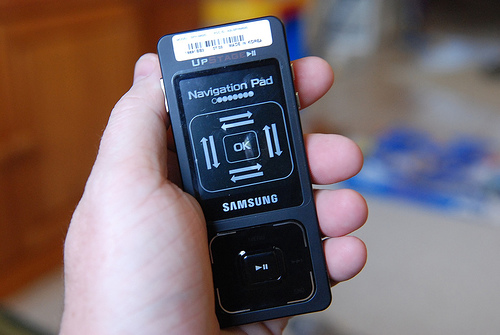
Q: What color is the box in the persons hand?
A: Black.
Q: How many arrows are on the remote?
A: 8.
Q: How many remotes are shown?
A: 1.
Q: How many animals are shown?
A: 0.